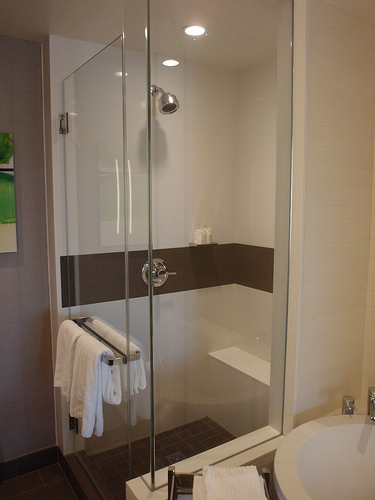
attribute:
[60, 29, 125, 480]
panel — glass, clear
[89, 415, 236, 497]
tile — brown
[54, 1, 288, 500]
shower — large, glass, clear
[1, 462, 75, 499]
floor — tiled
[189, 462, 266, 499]
towel — white, folded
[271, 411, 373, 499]
sink — white, round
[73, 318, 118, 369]
handle — metal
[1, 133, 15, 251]
picture — green, hanging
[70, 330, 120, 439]
towel — hanging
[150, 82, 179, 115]
fixture — metal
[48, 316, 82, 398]
towel — hanging